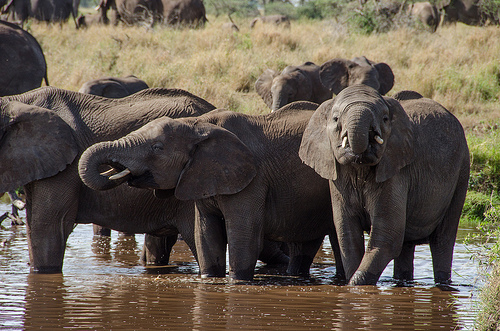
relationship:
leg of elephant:
[217, 191, 266, 277] [77, 99, 330, 269]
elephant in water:
[298, 84, 475, 288] [99, 269, 273, 329]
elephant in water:
[77, 99, 345, 280] [99, 269, 273, 329]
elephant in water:
[18, 81, 108, 281] [99, 269, 273, 329]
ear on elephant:
[298, 98, 342, 182] [298, 84, 473, 284]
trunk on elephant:
[72, 135, 147, 195] [77, 99, 330, 269]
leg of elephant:
[330, 194, 368, 281] [298, 84, 473, 284]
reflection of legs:
[393, 287, 458, 328] [332, 218, 459, 288]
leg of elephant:
[327, 180, 367, 282] [298, 84, 473, 284]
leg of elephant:
[347, 184, 407, 285] [298, 84, 473, 284]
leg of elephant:
[392, 244, 413, 279] [298, 84, 473, 284]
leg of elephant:
[428, 174, 468, 282] [298, 84, 473, 284]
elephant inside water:
[298, 84, 473, 284] [2, 210, 494, 323]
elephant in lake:
[77, 99, 345, 280] [0, 204, 495, 330]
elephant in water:
[77, 99, 345, 280] [92, 270, 187, 322]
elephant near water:
[298, 84, 475, 288] [2, 210, 494, 323]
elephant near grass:
[298, 84, 473, 284] [1, 13, 496, 228]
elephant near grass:
[77, 99, 330, 269] [1, 13, 496, 228]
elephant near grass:
[0, 84, 218, 274] [1, 13, 496, 228]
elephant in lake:
[298, 84, 475, 288] [0, 193, 500, 327]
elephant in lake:
[77, 99, 345, 280] [0, 209, 488, 324]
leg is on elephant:
[347, 190, 409, 285] [298, 84, 473, 284]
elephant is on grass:
[298, 84, 475, 288] [2, 28, 498, 220]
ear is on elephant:
[298, 98, 336, 180] [298, 84, 473, 284]